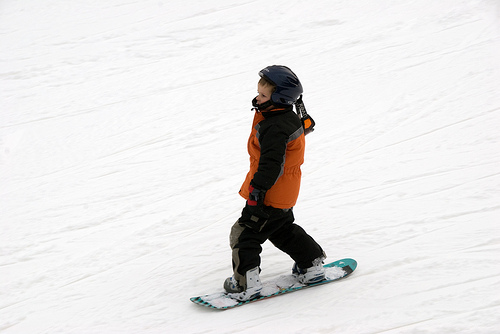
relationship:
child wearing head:
[229, 62, 332, 301] [251, 65, 302, 111]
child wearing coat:
[229, 62, 332, 301] [246, 111, 302, 211]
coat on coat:
[239, 109, 303, 209] [246, 111, 302, 211]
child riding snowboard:
[229, 62, 332, 301] [194, 253, 357, 306]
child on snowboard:
[229, 62, 332, 301] [194, 253, 357, 306]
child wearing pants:
[229, 62, 332, 301] [232, 207, 323, 271]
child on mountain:
[229, 62, 332, 301] [8, 8, 496, 322]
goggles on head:
[295, 98, 317, 131] [251, 65, 302, 111]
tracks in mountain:
[363, 151, 439, 218] [0, 0, 500, 334]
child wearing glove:
[229, 62, 332, 301] [249, 186, 265, 202]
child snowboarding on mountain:
[229, 62, 332, 301] [8, 8, 496, 322]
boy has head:
[229, 62, 332, 301] [251, 65, 302, 111]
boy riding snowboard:
[229, 62, 332, 301] [194, 253, 357, 306]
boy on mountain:
[229, 62, 332, 301] [0, 0, 500, 334]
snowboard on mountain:
[194, 253, 357, 306] [0, 0, 500, 334]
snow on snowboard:
[204, 294, 236, 306] [194, 253, 357, 306]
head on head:
[251, 65, 302, 111] [251, 63, 305, 114]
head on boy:
[251, 63, 305, 114] [229, 62, 332, 301]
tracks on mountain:
[363, 151, 439, 218] [0, 0, 500, 334]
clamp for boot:
[297, 265, 328, 282] [291, 262, 305, 281]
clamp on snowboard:
[297, 265, 328, 282] [194, 253, 357, 306]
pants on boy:
[232, 207, 323, 271] [229, 62, 332, 301]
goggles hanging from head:
[295, 98, 317, 131] [251, 65, 302, 111]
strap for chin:
[251, 106, 271, 111] [256, 108, 268, 112]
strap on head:
[251, 106, 271, 111] [251, 65, 302, 111]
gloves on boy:
[249, 186, 265, 202] [229, 62, 332, 301]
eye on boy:
[258, 94, 270, 101] [229, 62, 332, 301]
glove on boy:
[246, 185, 269, 218] [229, 62, 332, 301]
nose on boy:
[256, 95, 262, 99] [229, 62, 332, 301]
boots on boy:
[224, 254, 325, 301] [229, 62, 332, 301]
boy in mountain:
[229, 62, 332, 301] [0, 0, 500, 334]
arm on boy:
[257, 124, 278, 200] [229, 62, 332, 301]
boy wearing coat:
[229, 62, 332, 301] [246, 111, 302, 211]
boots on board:
[224, 254, 325, 301] [195, 268, 342, 289]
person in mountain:
[229, 62, 332, 301] [0, 0, 500, 334]